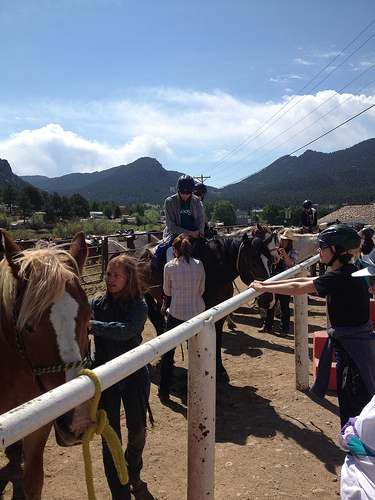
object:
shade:
[140, 360, 374, 486]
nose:
[63, 408, 103, 446]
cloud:
[74, 130, 288, 176]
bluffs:
[0, 140, 374, 198]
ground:
[0, 229, 373, 499]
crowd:
[90, 223, 373, 494]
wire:
[202, 19, 374, 191]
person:
[246, 223, 375, 432]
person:
[300, 198, 317, 235]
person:
[257, 225, 299, 338]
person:
[156, 235, 206, 402]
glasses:
[177, 189, 191, 195]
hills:
[3, 133, 372, 204]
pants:
[98, 369, 148, 492]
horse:
[0, 225, 95, 499]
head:
[0, 230, 102, 449]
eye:
[24, 319, 37, 337]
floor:
[208, 412, 300, 487]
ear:
[2, 230, 25, 274]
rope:
[52, 369, 128, 498]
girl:
[88, 252, 152, 495]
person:
[160, 173, 207, 315]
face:
[178, 189, 192, 200]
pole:
[3, 254, 320, 444]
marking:
[46, 284, 83, 378]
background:
[1, 141, 373, 214]